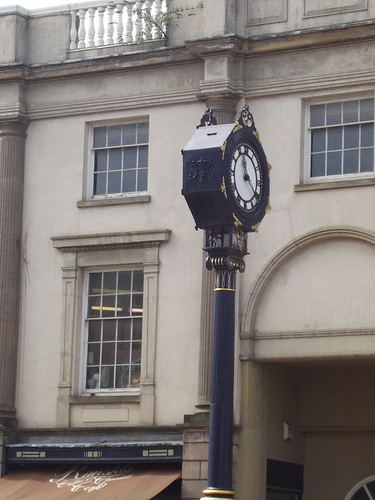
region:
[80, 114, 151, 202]
A window on the building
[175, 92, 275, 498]
A big blue and white clock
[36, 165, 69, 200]
Part of the white wall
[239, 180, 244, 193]
Part of the clock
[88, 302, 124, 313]
A light hanging on the wall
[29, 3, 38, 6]
Part of the sky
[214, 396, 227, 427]
Part of the clock's pole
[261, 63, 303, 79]
Part of the building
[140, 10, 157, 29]
Part of the green tree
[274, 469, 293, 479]
Part of the door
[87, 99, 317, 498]
A clock standing in front of a building.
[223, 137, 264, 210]
The clock face is white.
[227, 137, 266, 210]
The clock has roman numerals.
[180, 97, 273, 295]
The pole holding the clock has gold accents.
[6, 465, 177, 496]
A brown awning over a building.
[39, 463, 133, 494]
White writing on the awning.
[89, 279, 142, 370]
Lights are on the inside the window.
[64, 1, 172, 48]
A section of decorative white railing.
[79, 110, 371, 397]
The windows are trimmed in white.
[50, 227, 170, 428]
Decorative architectural design around the window.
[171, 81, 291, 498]
a tall clock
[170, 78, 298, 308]
a clock that is embellished and decorated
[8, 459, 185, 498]
a faded brown awning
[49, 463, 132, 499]
white cursive text on the awning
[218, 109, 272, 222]
the clock has a white face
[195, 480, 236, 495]
gold trimming on the clock post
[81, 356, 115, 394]
there is a small fan seen in the window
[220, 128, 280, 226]
the clock face has roman numerals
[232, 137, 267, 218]
the roman numerals are black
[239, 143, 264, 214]
the clock has black minute and hour hands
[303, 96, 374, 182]
window on the exterior of a stone building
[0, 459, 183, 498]
brown fabric awning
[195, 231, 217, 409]
stone column behind clock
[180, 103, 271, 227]
black clock on top of a post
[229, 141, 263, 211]
white clock face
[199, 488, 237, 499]
gold stripes around pole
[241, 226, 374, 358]
arch over an entryway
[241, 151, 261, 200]
black hands on front of clock face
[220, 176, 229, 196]
gold details around clock face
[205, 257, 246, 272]
gold scrolls under clock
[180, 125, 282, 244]
black and white clock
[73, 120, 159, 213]
small window on the side of the building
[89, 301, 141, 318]
lights visible through the window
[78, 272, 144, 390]
white lines on the window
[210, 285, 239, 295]
gold stripe around the pole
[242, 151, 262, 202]
two black clock hands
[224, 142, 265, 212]
roman numerals around the circumference of the clcok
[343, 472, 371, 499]
corner of a window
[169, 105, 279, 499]
clock on a pole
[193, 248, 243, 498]
black and gold pole